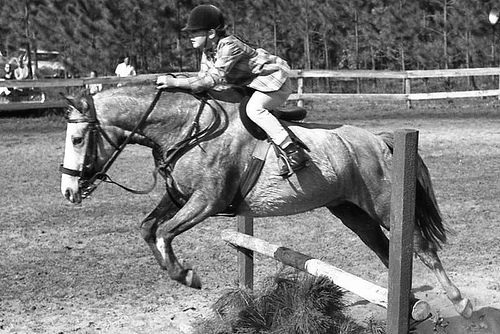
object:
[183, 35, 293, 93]
jacket